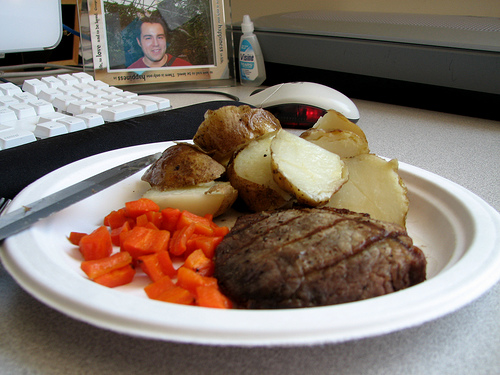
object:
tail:
[136, 78, 241, 103]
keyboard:
[0, 126, 38, 153]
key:
[59, 116, 86, 134]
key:
[35, 118, 70, 141]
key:
[38, 110, 68, 127]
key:
[102, 104, 148, 124]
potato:
[139, 103, 410, 228]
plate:
[2, 135, 499, 351]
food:
[63, 102, 429, 310]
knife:
[5, 150, 167, 241]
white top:
[274, 81, 334, 103]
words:
[118, 69, 178, 84]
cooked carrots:
[67, 195, 231, 308]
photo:
[100, 0, 221, 67]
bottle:
[236, 13, 265, 86]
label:
[238, 37, 259, 83]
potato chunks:
[269, 129, 346, 206]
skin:
[155, 152, 217, 173]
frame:
[87, 4, 229, 86]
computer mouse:
[230, 78, 365, 125]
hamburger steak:
[205, 205, 429, 309]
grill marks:
[237, 218, 381, 253]